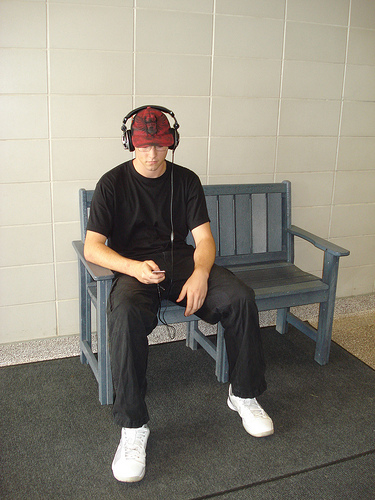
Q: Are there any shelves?
A: No, there are no shelves.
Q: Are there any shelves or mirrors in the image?
A: No, there are no shelves or mirrors.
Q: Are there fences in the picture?
A: No, there are no fences.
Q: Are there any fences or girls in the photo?
A: No, there are no fences or girls.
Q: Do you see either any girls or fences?
A: No, there are no fences or girls.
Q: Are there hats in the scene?
A: Yes, there is a hat.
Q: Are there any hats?
A: Yes, there is a hat.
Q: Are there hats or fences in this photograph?
A: Yes, there is a hat.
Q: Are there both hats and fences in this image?
A: No, there is a hat but no fences.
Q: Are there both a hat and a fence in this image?
A: No, there is a hat but no fences.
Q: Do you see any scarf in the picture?
A: No, there are no scarves.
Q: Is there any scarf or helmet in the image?
A: No, there are no scarves or helmets.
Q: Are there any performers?
A: No, there are no performers.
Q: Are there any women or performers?
A: No, there are no performers or women.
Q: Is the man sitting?
A: Yes, the man is sitting.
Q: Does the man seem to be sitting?
A: Yes, the man is sitting.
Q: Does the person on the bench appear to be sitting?
A: Yes, the man is sitting.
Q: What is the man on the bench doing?
A: The man is sitting.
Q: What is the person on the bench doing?
A: The man is sitting.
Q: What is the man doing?
A: The man is sitting.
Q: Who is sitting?
A: The man is sitting.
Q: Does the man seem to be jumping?
A: No, the man is sitting.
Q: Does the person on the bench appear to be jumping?
A: No, the man is sitting.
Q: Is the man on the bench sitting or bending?
A: The man is sitting.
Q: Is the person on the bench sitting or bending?
A: The man is sitting.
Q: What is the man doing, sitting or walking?
A: The man is sitting.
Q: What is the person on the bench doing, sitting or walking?
A: The man is sitting.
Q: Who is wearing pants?
A: The man is wearing pants.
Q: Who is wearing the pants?
A: The man is wearing pants.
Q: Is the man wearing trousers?
A: Yes, the man is wearing trousers.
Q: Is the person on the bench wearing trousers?
A: Yes, the man is wearing trousers.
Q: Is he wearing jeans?
A: No, the man is wearing trousers.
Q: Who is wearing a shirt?
A: The man is wearing a shirt.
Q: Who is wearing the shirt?
A: The man is wearing a shirt.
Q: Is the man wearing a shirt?
A: Yes, the man is wearing a shirt.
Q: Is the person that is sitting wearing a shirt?
A: Yes, the man is wearing a shirt.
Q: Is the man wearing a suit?
A: No, the man is wearing a shirt.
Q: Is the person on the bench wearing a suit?
A: No, the man is wearing a shirt.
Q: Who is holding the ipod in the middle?
A: The man is holding the ipod.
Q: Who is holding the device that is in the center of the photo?
A: The man is holding the ipod.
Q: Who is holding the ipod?
A: The man is holding the ipod.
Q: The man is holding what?
A: The man is holding the ipod.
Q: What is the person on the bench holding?
A: The man is holding the ipod.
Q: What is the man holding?
A: The man is holding the ipod.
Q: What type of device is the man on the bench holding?
A: The man is holding the ipod.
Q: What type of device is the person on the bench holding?
A: The man is holding the ipod.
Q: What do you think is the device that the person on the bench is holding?
A: The device is an ipod.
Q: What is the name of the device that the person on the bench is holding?
A: The device is an ipod.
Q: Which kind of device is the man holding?
A: The man is holding the ipod.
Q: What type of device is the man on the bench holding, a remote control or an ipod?
A: The man is holding an ipod.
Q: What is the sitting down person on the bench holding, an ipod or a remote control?
A: The man is holding an ipod.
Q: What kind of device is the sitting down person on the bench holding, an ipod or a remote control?
A: The man is holding an ipod.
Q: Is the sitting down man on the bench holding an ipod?
A: Yes, the man is holding an ipod.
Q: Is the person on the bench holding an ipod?
A: Yes, the man is holding an ipod.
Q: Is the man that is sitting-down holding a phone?
A: No, the man is holding an ipod.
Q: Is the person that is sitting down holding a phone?
A: No, the man is holding an ipod.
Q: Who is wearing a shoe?
A: The man is wearing a shoe.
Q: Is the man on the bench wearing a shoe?
A: Yes, the man is wearing a shoe.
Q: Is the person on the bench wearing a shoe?
A: Yes, the man is wearing a shoe.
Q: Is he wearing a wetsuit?
A: No, the man is wearing a shoe.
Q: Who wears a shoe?
A: The man wears a shoe.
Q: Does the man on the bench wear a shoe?
A: Yes, the man wears a shoe.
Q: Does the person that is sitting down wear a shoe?
A: Yes, the man wears a shoe.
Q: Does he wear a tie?
A: No, the man wears a shoe.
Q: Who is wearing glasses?
A: The man is wearing glasses.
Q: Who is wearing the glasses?
A: The man is wearing glasses.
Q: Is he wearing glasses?
A: Yes, the man is wearing glasses.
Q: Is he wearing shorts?
A: No, the man is wearing glasses.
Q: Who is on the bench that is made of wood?
A: The man is on the bench.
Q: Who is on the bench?
A: The man is on the bench.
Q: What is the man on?
A: The man is on the bench.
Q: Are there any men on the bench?
A: Yes, there is a man on the bench.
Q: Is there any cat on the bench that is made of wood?
A: No, there is a man on the bench.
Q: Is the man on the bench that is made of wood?
A: Yes, the man is on the bench.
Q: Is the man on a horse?
A: No, the man is on the bench.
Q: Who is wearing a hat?
A: The man is wearing a hat.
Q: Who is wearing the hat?
A: The man is wearing a hat.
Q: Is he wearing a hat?
A: Yes, the man is wearing a hat.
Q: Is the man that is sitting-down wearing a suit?
A: No, the man is wearing a hat.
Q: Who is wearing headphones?
A: The man is wearing headphones.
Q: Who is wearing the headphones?
A: The man is wearing headphones.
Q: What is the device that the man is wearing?
A: The device is headphones.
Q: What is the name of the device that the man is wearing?
A: The device is headphones.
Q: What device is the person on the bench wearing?
A: The man is wearing headphones.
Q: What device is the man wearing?
A: The man is wearing headphones.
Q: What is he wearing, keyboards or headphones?
A: The man is wearing headphones.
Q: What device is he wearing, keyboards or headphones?
A: The man is wearing headphones.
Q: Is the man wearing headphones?
A: Yes, the man is wearing headphones.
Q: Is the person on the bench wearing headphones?
A: Yes, the man is wearing headphones.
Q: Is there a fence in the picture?
A: No, there are no fences.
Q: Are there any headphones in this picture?
A: Yes, there are headphones.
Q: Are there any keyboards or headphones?
A: Yes, there are headphones.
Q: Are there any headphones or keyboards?
A: Yes, there are headphones.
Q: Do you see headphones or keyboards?
A: Yes, there are headphones.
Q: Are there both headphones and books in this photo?
A: No, there are headphones but no books.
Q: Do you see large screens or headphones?
A: Yes, there are large headphones.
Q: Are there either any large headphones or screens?
A: Yes, there are large headphones.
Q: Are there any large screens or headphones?
A: Yes, there are large headphones.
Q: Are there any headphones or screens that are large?
A: Yes, the headphones are large.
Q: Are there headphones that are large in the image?
A: Yes, there are large headphones.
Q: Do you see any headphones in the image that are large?
A: Yes, there are headphones that are large.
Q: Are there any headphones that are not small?
A: Yes, there are large headphones.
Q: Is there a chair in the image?
A: No, there are no chairs.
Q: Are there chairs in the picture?
A: No, there are no chairs.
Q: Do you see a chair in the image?
A: No, there are no chairs.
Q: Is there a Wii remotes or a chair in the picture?
A: No, there are no chairs or Wii controllers.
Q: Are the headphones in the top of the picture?
A: Yes, the headphones are in the top of the image.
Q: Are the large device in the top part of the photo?
A: Yes, the headphones are in the top of the image.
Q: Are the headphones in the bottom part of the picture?
A: No, the headphones are in the top of the image.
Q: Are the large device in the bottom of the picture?
A: No, the headphones are in the top of the image.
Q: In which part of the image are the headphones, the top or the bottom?
A: The headphones are in the top of the image.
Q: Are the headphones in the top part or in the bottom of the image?
A: The headphones are in the top of the image.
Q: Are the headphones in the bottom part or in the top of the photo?
A: The headphones are in the top of the image.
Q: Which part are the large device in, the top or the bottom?
A: The headphones are in the top of the image.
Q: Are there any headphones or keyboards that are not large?
A: No, there are headphones but they are large.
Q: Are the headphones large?
A: Yes, the headphones are large.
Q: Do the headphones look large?
A: Yes, the headphones are large.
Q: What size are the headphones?
A: The headphones are large.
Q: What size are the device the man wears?
A: The headphones are large.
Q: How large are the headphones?
A: The headphones are large.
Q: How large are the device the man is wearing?
A: The headphones are large.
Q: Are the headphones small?
A: No, the headphones are large.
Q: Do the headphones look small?
A: No, the headphones are large.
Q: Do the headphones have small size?
A: No, the headphones are large.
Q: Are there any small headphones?
A: No, there are headphones but they are large.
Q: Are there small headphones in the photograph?
A: No, there are headphones but they are large.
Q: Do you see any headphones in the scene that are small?
A: No, there are headphones but they are large.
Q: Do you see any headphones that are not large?
A: No, there are headphones but they are large.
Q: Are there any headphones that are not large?
A: No, there are headphones but they are large.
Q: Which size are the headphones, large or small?
A: The headphones are large.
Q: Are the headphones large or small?
A: The headphones are large.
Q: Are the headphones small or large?
A: The headphones are large.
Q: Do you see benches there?
A: Yes, there is a bench.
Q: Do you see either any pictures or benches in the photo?
A: Yes, there is a bench.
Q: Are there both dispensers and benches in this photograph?
A: No, there is a bench but no dispensers.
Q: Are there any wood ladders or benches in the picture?
A: Yes, there is a wood bench.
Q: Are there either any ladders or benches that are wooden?
A: Yes, the bench is wooden.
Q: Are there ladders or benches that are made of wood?
A: Yes, the bench is made of wood.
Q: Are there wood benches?
A: Yes, there is a bench that is made of wood.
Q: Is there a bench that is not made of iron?
A: Yes, there is a bench that is made of wood.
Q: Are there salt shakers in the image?
A: No, there are no salt shakers.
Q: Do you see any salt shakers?
A: No, there are no salt shakers.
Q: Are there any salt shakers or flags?
A: No, there are no salt shakers or flags.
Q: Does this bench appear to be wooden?
A: Yes, the bench is wooden.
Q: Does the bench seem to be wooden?
A: Yes, the bench is wooden.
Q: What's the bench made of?
A: The bench is made of wood.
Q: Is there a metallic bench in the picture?
A: No, there is a bench but it is wooden.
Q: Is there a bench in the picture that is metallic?
A: No, there is a bench but it is wooden.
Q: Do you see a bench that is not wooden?
A: No, there is a bench but it is wooden.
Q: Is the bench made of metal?
A: No, the bench is made of wood.